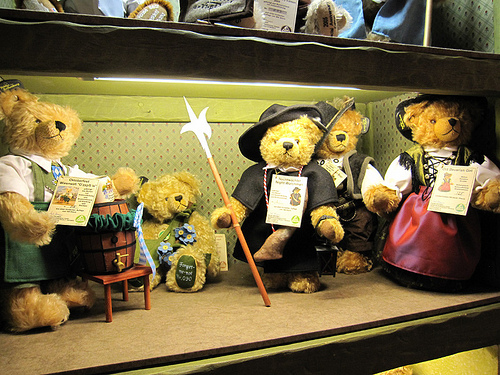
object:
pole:
[180, 95, 271, 306]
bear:
[234, 102, 344, 297]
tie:
[157, 220, 181, 244]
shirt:
[0, 154, 99, 202]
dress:
[381, 145, 483, 281]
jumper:
[0, 152, 70, 283]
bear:
[2, 86, 95, 330]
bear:
[383, 94, 500, 290]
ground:
[405, 108, 418, 121]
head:
[259, 114, 324, 169]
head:
[137, 169, 201, 224]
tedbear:
[128, 169, 220, 293]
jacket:
[231, 160, 339, 273]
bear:
[130, 169, 221, 295]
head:
[403, 100, 473, 149]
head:
[0, 89, 84, 158]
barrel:
[78, 199, 136, 275]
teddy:
[313, 96, 403, 274]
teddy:
[0, 86, 140, 332]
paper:
[427, 163, 477, 216]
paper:
[322, 161, 347, 188]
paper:
[265, 174, 308, 228]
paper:
[214, 234, 228, 272]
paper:
[48, 176, 100, 227]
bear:
[0, 85, 139, 332]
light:
[93, 77, 362, 91]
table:
[0, 264, 500, 375]